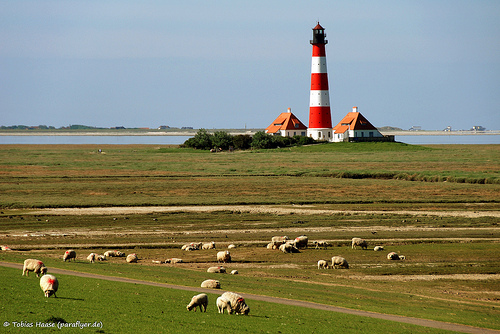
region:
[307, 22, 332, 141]
red and white light house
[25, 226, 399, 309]
sheep grazing on the field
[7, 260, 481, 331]
small road way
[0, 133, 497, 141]
the water is calm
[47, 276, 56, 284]
red marking on the sheep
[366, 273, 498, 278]
a patch of dirt on the ground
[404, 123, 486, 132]
buildings on the horizon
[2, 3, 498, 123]
clear blue skies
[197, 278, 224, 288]
sheep is laying down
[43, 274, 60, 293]
the sheep has a red mark on it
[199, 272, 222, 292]
the sheep is laying down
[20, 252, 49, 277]
the sheep is standing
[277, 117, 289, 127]
the roof is brown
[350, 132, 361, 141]
the house is white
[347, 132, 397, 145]
the house has a wooden deck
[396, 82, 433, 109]
the sky is blue gray in color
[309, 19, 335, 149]
Large red and white lighthouse.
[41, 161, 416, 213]
Green grassy terrain.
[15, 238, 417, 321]
Multiple sheep in a field.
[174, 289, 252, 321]
Three sheep grazing.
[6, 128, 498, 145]
Blue body of water.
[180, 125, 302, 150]
Green trees near lighthouse.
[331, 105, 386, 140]
White and red peaked building.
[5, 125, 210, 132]
Sandy shoreline.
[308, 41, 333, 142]
Horizontal red and white stripes.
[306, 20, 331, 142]
a red and white lighthouse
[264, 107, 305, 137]
orange and white house to the left of the lighthouse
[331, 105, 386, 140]
house to the right of the lighthouse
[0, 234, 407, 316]
sheep in the field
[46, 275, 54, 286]
red paint on a sheep's back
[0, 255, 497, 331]
a dirt path in a field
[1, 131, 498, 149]
a strip of ocean water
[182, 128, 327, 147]
trees beside the lighthouse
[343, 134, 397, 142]
a brick wall alongside a house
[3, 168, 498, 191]
a long trench in a field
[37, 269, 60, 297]
sheep stands in field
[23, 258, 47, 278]
sheep stands in field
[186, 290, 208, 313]
sheep stands in field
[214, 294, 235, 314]
sheep stands in field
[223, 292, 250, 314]
sheep stands in field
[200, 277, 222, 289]
sheep stands in field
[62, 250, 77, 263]
sheep stands in field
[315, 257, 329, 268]
sheep stands in field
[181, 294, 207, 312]
A sheep in a field of grass.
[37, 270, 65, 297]
A sheep in a field of grass.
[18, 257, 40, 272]
A sheep in a field of grass.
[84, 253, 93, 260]
A sheep in a field of grass.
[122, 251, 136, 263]
A sheep in a field of grass.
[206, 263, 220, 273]
A sheep in a field of grass.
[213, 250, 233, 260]
A sheep in a field of grass.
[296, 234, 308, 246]
A sheep in a field of grass.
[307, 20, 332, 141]
The red and white lighthouse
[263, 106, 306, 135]
The house below the lighthouse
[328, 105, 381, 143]
The house below the lighthouse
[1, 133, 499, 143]
The water behind the lighthouse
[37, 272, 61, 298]
The white sheep with the red marking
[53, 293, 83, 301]
The shadow of the sheep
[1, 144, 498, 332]
The field full of sheep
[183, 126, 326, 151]
The trees in front of the lighthouse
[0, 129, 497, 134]
The sandbar across form the water